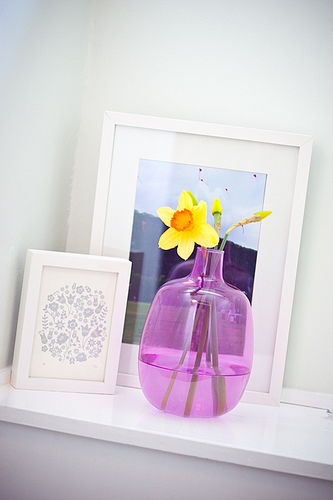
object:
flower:
[157, 189, 220, 261]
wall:
[0, 0, 333, 392]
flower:
[210, 197, 222, 229]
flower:
[224, 211, 272, 237]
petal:
[158, 227, 178, 250]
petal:
[156, 206, 176, 227]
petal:
[177, 189, 193, 209]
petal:
[193, 200, 207, 223]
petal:
[193, 221, 220, 248]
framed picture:
[88, 111, 314, 408]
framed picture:
[9, 249, 132, 392]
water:
[138, 353, 250, 417]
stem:
[179, 232, 228, 366]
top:
[23, 247, 131, 272]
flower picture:
[139, 190, 272, 417]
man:
[221, 306, 226, 319]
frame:
[86, 109, 314, 407]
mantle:
[0, 388, 332, 481]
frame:
[10, 249, 132, 396]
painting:
[122, 160, 266, 358]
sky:
[135, 159, 266, 249]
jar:
[137, 247, 253, 418]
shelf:
[0, 384, 333, 498]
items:
[10, 248, 132, 397]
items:
[88, 108, 314, 406]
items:
[138, 188, 272, 418]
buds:
[211, 198, 222, 215]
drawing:
[38, 283, 108, 365]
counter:
[1, 386, 332, 500]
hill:
[131, 209, 257, 302]